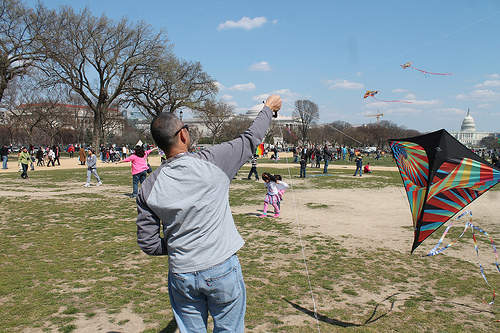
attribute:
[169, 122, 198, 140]
specks — black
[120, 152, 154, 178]
t-shirt — pink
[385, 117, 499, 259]
kite — multicolored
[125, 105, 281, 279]
shirt — long sleeve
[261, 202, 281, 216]
tights — PINK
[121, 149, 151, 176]
sweater — PINK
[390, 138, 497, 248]
design — geometric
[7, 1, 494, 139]
sky — blue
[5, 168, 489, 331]
spots — bare 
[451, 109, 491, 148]
building — white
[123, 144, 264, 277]
shirt — gray, grey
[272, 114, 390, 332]
kite string — white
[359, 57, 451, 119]
kites — colorful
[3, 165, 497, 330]
grass — green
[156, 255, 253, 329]
jeans — BLUE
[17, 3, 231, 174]
tall trees — Tall , leafless 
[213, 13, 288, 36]
white clouds — Small